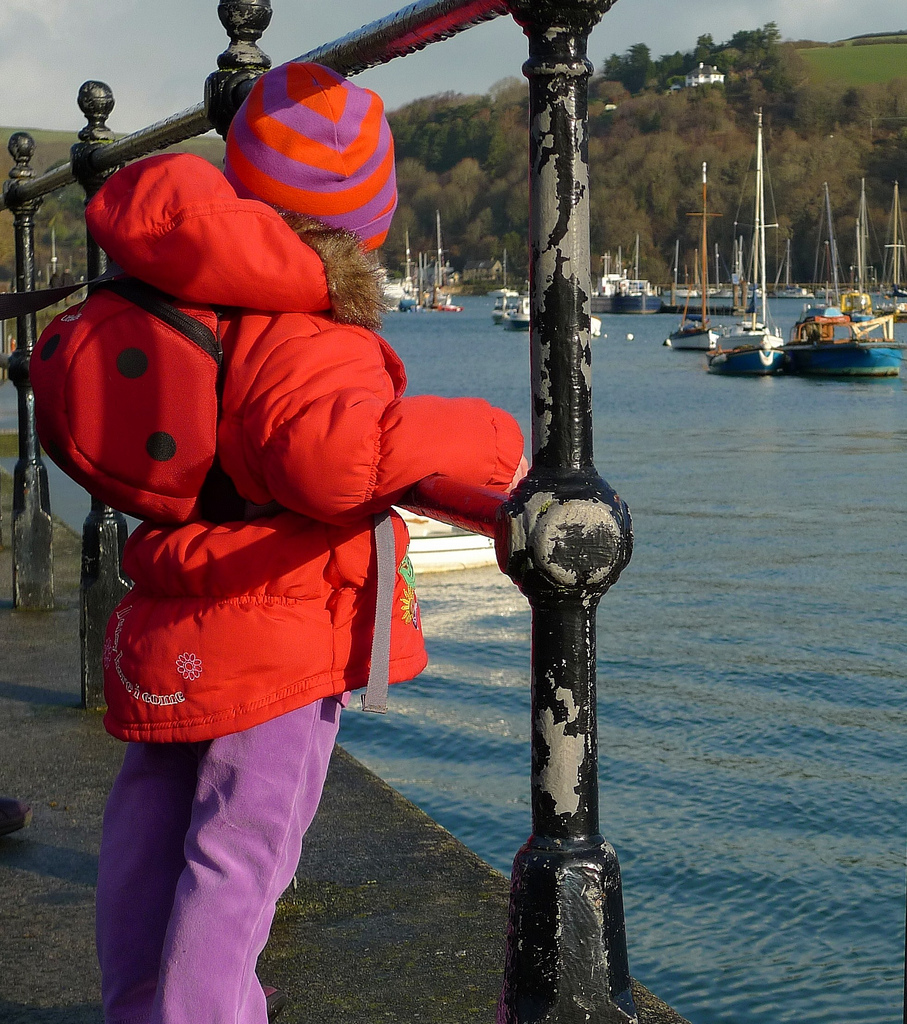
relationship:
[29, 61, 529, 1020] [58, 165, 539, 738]
girl in jacket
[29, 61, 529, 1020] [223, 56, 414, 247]
girl with a hat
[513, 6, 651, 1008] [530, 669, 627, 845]
metal railing with chipped paint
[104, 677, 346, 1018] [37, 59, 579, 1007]
purple pants on little girl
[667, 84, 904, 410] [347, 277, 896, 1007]
sailboats floating on water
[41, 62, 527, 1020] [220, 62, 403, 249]
girl wearing a knit cap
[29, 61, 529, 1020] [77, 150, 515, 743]
girl wearing a jacket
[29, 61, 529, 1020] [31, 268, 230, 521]
girl wearing a backpack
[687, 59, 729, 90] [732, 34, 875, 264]
house built on a hill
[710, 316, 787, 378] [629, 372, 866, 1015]
boat floating on water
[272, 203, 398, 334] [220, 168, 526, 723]
fur on top of jacket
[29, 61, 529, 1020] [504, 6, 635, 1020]
girl holding railing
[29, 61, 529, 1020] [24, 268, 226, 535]
girl wearing a backpack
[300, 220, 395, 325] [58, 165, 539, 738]
fur attached to a jacket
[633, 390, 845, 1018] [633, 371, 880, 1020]
water filling river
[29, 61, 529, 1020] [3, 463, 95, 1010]
girl standing on walkway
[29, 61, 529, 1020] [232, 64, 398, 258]
girl wearing a hat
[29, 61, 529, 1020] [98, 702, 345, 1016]
girl wearing pants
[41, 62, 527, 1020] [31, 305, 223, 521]
girl wearing a backpack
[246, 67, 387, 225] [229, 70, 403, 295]
hat on top of head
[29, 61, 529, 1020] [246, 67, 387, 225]
girl wearing a hat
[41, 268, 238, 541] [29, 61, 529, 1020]
backpack on girl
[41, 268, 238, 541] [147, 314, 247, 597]
backpack on back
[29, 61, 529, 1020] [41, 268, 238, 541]
girl wearing a backpack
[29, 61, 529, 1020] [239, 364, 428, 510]
girl wearing a coat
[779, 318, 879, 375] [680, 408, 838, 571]
sailboats in water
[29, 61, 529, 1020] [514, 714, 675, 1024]
girl standing near black railing